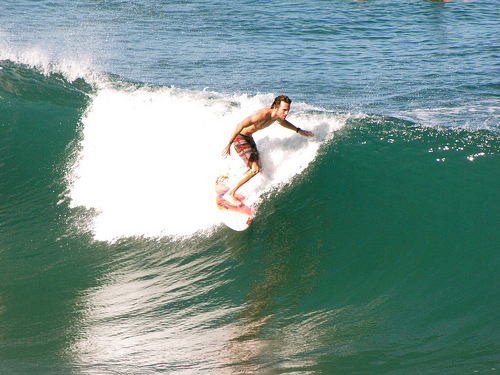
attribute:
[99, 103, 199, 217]
wave — white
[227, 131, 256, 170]
stripe — red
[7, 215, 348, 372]
wave front — gentle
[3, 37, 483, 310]
water — Black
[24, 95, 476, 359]
water — flowing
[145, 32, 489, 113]
water — calm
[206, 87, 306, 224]
person — surfing